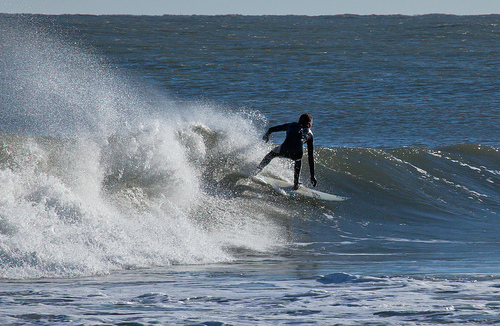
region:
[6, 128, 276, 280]
Waves in the ocean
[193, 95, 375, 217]
A person surfing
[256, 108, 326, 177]
A person in a wetsuit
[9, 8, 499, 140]
The blue ocean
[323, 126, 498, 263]
A calm wave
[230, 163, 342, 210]
A surfboard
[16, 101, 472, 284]
A person riding the surf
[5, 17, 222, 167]
Water spraying from the waves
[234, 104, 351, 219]
A person on top of a surfboard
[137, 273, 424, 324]
The calm ocean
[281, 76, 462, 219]
the sea is green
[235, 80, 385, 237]
the sea is green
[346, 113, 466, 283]
the sea is green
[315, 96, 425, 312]
the sea is green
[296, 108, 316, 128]
the head of a man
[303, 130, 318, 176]
the arm of a man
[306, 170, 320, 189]
the hand of a man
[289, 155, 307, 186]
the leg of a man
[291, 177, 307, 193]
the foot of a man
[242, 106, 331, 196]
a man on the surfboard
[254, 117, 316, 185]
a black wet suit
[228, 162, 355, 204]
a white surfboard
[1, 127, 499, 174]
the crest of a wave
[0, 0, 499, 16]
a clear blue sky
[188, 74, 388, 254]
surfer riding a wave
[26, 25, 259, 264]
tall splash of water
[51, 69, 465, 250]
medium sized wave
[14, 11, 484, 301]
surfer on a wave in the ocean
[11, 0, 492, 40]
blue sky above blue water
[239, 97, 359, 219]
man wearing a dark wetsuit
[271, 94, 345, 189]
surfer with dark hair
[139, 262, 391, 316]
ripples on ocean water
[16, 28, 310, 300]
white spray above a wave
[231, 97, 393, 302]
surfer on a white surfboard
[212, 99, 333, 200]
man surfing in ocean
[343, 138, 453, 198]
wave from the ocean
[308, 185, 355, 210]
front of a surfboard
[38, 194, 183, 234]
white foam from wave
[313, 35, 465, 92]
water of an ocean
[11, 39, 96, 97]
water splashing from waves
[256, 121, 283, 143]
right arm of a surfer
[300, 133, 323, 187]
left arm of a surfer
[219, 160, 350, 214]
white surfboard in ocean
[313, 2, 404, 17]
blue sky on the horizon